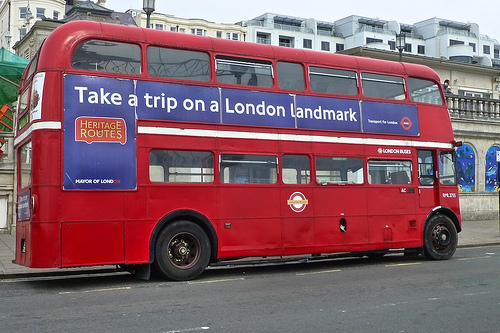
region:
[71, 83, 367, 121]
"Take a trip on a london landmark"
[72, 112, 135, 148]
"Heritage routes" company logo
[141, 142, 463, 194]
Bottom deck windows of double decker bus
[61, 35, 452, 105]
Top deck windows of double decker bus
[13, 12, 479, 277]
Red double decker london tour bus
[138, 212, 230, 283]
Back wheel of tour bus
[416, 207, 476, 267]
Front wheel of tour bus (spare wheel)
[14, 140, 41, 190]
Back window of tour bus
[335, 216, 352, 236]
Gas input for tour bus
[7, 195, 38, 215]
Tail lights on double decker tour bus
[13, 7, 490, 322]
a red double decker London tour bus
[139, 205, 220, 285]
black back wheel of the bus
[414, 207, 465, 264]
black front wheel of the bus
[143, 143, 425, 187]
rectangular windows of the bus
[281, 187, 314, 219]
red, yellow, and white bus logo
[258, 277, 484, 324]
gray pavement on the street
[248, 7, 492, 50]
rooftops of buildings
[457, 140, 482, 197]
blue mural on the side of the road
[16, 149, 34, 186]
back window of the bus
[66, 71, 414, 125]
blue and white bus advertisement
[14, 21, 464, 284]
a double decker red bus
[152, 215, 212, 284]
a bus rear tire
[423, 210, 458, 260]
a bus front tire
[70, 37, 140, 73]
a bus passenger window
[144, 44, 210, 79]
a bus passenger window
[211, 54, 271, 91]
a bus passenger window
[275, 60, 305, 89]
a bus passenger window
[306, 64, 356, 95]
a bus passenger window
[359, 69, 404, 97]
a bus passenger window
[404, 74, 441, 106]
a bus passenger window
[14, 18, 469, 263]
the double decker bus on the street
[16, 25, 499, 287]
the double decker bus is empty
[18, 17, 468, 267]
the double decker bus is red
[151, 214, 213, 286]
the rear tire of the bus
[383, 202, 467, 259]
the front tire of the bus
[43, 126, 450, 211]
the first deck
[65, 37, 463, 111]
the second deck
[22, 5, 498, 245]
the buildings behind the bus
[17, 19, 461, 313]
the bus is parked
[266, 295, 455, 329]
the street is paved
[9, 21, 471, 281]
the red bus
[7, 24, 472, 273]
the red double decker bus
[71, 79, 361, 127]
the big white words on the side of the bus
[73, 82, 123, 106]
the word on the bus that says Take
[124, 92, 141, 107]
the letter "a" on the bus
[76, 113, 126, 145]
the words HERITAGE ROUTES on the bus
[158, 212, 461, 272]
the two wheels on the side of the bus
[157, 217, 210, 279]
the back wheel on the bus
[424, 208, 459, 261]
the front wheel of the bus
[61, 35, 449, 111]
the passenger windows on the top deck of the bus